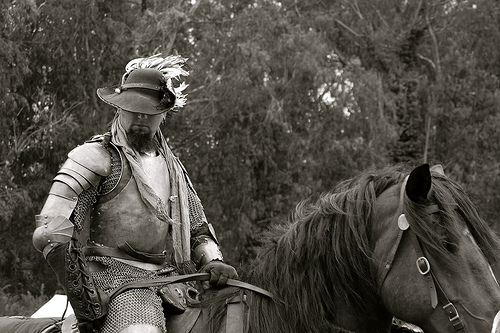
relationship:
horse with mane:
[6, 161, 496, 330] [188, 160, 498, 332]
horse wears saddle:
[6, 161, 496, 330] [33, 264, 243, 331]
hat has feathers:
[96, 55, 188, 115] [124, 52, 190, 112]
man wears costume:
[31, 53, 238, 329] [32, 120, 224, 330]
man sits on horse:
[31, 53, 238, 329] [6, 161, 496, 330]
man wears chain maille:
[31, 53, 238, 329] [59, 139, 212, 331]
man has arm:
[31, 64, 238, 329] [31, 155, 106, 331]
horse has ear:
[6, 161, 496, 330] [403, 162, 433, 207]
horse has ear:
[6, 161, 496, 330] [426, 163, 446, 180]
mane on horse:
[237, 162, 405, 332] [6, 161, 496, 330]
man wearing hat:
[31, 53, 238, 329] [91, 51, 195, 120]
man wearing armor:
[31, 64, 238, 329] [33, 139, 228, 329]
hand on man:
[203, 252, 250, 284] [31, 53, 238, 329]